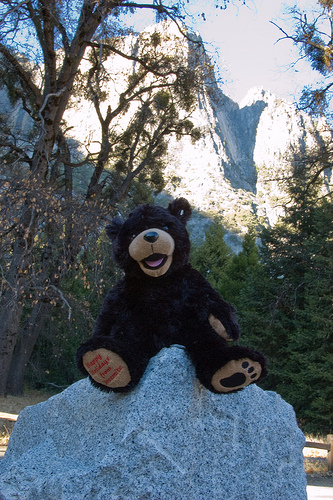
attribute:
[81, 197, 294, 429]
bear — teddy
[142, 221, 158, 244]
nose — black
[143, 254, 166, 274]
tongue — pink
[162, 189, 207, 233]
ear — brown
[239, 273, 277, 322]
leaf — green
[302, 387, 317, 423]
leaf — green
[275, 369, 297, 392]
leaf — green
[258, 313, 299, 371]
leaf — green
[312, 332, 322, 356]
leaf — green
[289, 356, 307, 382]
leaf — green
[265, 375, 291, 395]
leaf — green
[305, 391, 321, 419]
leaf — green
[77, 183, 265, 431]
bear — teddy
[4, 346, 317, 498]
rock — blue gray, granite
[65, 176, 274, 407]
bear — teddy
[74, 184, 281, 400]
bear — teddy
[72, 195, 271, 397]
teddy bear — brown, black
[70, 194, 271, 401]
bear — teddy, stuffed, toy, black, large, plush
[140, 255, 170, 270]
tongue — pink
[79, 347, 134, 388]
bottom — brown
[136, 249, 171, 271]
mouth — open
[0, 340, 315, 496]
stone — grey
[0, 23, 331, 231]
mountain — sunlit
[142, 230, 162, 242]
nose — brown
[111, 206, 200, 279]
face — light brown, dark brown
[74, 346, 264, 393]
paws — brown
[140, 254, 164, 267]
tongue — pink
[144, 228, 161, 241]
nose — black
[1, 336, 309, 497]
boulder — huge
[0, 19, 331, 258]
mountains — huge, pictured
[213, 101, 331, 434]
tree — tall, green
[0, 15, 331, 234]
mountains — tall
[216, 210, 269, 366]
tree — green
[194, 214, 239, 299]
tree — tall, green